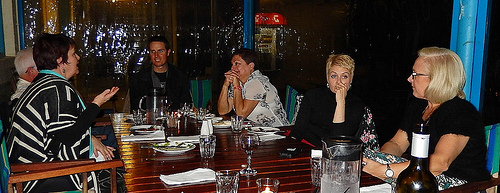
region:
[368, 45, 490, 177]
person sitting at table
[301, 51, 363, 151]
person sitting at table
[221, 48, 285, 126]
person sitting at table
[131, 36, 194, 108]
person sitting at table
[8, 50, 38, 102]
person sitting at table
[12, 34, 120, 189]
person sitting at table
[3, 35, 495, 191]
group of men and women sitting at a table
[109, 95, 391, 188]
table with glasses, napkins and plates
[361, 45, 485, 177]
woman wearing glasses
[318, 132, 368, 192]
water pitcher on table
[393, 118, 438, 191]
brown bottle sitting on table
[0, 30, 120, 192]
woman sitting in chair at table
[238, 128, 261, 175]
wine glass on table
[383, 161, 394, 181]
wristwatch on woman's arm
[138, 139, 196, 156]
plate and eating utensils on table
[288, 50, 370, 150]
woman gazing off in the distance, hand at face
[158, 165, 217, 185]
rumpled cloth napkin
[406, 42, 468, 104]
pageboy haircut parted on the side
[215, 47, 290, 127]
woman with her hands folded in front of her face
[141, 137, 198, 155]
salad plate with knife and fork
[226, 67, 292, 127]
white nylon blouse with black print design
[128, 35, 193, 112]
man with a tanned face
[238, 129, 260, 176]
half full wine glass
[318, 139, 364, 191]
half full pitcher of ice water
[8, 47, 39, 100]
white haired man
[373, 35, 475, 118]
head of a woman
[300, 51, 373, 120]
woman not facing group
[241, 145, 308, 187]
brown table in front of people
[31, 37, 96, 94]
woman talking to people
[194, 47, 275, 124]
woman with arms on table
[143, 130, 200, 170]
plate in front of woman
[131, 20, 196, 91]
man sitting at the table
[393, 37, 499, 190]
a person sitting at table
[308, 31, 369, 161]
a person sitting at table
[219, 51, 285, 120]
a person sitting at table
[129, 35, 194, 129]
a person sitting at table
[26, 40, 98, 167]
a person sitting at table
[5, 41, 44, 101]
a person sitting at table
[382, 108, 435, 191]
a bottle on table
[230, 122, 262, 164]
a glass on table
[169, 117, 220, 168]
a glass on table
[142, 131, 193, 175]
a plate on table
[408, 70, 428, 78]
WOMAN HAS ON EYE GLASSES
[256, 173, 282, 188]
CUP COASTER ON THE TABLE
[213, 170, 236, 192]
CLEAR GLASS ON THE TABLE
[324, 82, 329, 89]
LADY WEARING EARRING IN THE EAR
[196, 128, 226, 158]
A glass of water on the table.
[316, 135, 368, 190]
A pitcher of water on the table.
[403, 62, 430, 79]
The lady is wearing glasses.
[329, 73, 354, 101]
The woman has her hand by her mouth.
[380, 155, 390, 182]
The lady is wearing a watch.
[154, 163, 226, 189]
A white napkin on the table.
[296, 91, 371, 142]
The shirt is black.